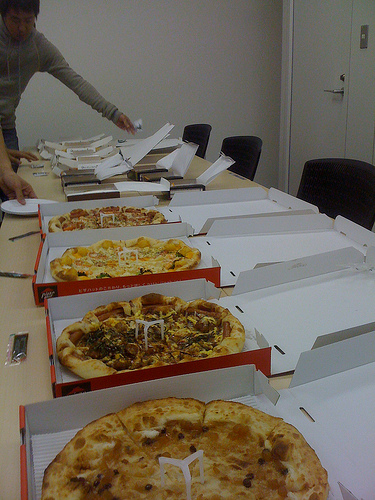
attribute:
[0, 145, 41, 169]
hand — one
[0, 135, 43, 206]
hand — one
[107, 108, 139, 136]
hand — one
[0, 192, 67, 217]
plate — circular, white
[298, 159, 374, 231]
chair — dark 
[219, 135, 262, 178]
chair — dark 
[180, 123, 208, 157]
chair — dark 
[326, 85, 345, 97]
handle — one, shiny, metal door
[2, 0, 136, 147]
person — gray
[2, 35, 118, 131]
shirt — long sleeved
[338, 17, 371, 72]
switchplate — light metal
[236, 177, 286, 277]
lid — white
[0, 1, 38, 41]
hair — short dark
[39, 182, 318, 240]
box — white, cardboard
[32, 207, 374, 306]
box — white, cardboard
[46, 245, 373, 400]
box — white, cardboard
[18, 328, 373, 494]
box — white, cardboard